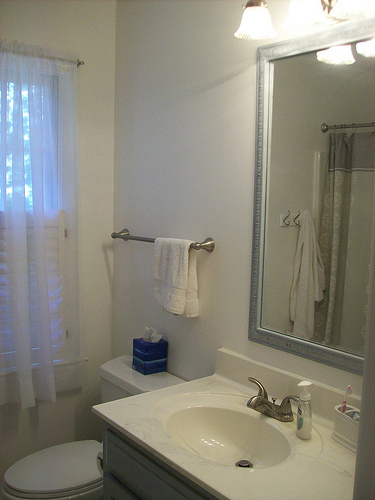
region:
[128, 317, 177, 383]
bright blue tissue box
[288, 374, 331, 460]
pump bottle of hand soap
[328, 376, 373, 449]
white toothbrush holder with toothbrush in it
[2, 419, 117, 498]
white commode with lid down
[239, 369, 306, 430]
metal sink faucet in bathroom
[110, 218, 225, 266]
metal towel bar hung above commode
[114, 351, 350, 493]
off white sink in bathroom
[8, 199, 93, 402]
white shutters in bathroom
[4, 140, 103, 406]
long white shears in bathroom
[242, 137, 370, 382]
mirror on bathroom wall with silver frame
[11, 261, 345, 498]
Small white close bathroom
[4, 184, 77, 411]
Window curtains sheer white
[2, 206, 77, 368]
White indoor window shutters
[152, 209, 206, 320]
White hand towel hangs fixture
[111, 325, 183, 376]
Blue pop-up square tissue box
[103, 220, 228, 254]
Metal silver towel bar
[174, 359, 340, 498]
Oval shaped basin sink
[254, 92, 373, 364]
Mirror reflection opposite wall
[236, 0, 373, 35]
Overhead tulip shade lighting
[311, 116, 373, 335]
Print tan shower curtain mirror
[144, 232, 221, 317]
White hand towel on a bar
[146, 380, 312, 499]
Sink and counter top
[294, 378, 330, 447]
Hand soap by a sink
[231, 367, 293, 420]
Silver faucet on a sink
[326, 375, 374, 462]
Toothbrush holder on a counter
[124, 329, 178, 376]
Blue tissue box on a toilet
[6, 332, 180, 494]
White toilet in a bathroom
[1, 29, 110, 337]
Curtain on a window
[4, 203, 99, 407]
Shutter in a window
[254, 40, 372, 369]
Mirror on a wall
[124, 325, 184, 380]
BLUE BOX ON TOILET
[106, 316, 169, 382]
BLUE BOX ON TOILET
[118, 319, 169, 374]
BLUE BOX ON TOILET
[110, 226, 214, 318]
white towel on rod in bathroom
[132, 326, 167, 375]
blue box of white tissue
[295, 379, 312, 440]
hand soap on top of sink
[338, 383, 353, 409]
red and white toothbrush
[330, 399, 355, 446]
white toothbrush holder on the sink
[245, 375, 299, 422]
metal faucet on top of sink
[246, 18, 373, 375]
mirror affixed to bathroom's wall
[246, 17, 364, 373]
mirror above the sink in the bathroom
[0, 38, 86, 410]
white sheer curtain over the window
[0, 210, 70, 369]
wooden blinds behind the sheer curtain